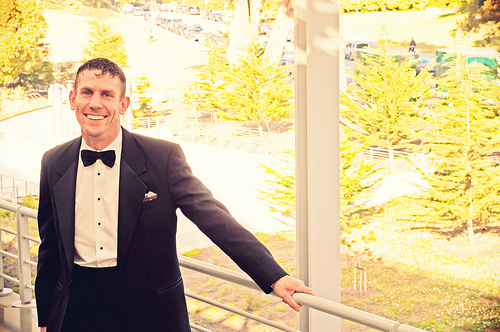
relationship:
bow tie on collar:
[81, 149, 116, 168] [76, 125, 150, 146]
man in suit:
[35, 57, 317, 332] [35, 125, 290, 329]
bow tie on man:
[78, 150, 117, 164] [35, 57, 317, 332]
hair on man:
[76, 57, 127, 80] [35, 57, 317, 332]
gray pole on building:
[291, 0, 344, 327] [1, 2, 353, 329]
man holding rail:
[12, 69, 226, 329] [212, 254, 416, 316]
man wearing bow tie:
[35, 57, 317, 332] [78, 145, 120, 172]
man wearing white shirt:
[35, 57, 317, 332] [75, 164, 126, 270]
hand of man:
[269, 272, 316, 314] [35, 57, 317, 332]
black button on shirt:
[97, 173, 100, 176] [73, 141, 121, 266]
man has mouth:
[35, 57, 317, 332] [73, 109, 115, 123]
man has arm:
[35, 57, 317, 332] [192, 198, 255, 263]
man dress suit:
[35, 57, 317, 332] [34, 125, 289, 332]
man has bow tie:
[35, 57, 317, 332] [78, 149, 115, 166]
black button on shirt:
[95, 168, 103, 177] [73, 126, 122, 269]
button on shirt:
[98, 197, 101, 200] [73, 126, 123, 267]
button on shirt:
[92, 191, 104, 203] [23, 140, 236, 317]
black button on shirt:
[97, 173, 100, 176] [73, 126, 123, 267]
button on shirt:
[95, 221, 101, 226] [73, 126, 123, 267]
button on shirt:
[99, 245, 104, 250] [73, 126, 123, 267]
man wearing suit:
[35, 57, 317, 332] [35, 125, 290, 329]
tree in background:
[393, 49, 495, 243] [347, 21, 480, 291]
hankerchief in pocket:
[142, 190, 158, 200] [138, 195, 160, 207]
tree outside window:
[348, 50, 426, 179] [4, 10, 480, 329]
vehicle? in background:
[187, 4, 199, 15] [3, 14, 484, 90]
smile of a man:
[83, 110, 110, 121] [35, 57, 317, 332]